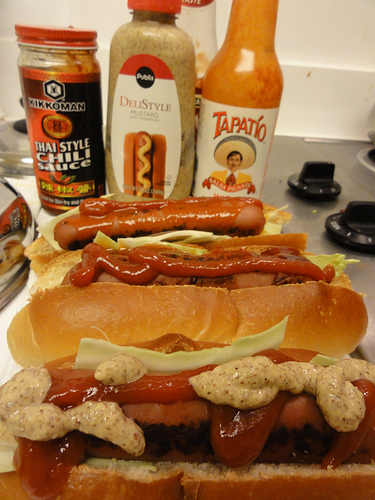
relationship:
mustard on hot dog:
[2, 348, 374, 459] [44, 350, 373, 463]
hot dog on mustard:
[44, 350, 373, 463] [2, 348, 374, 459]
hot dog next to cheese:
[44, 350, 373, 463] [72, 313, 288, 375]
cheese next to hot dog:
[72, 313, 288, 375] [44, 350, 373, 463]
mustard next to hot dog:
[2, 348, 374, 459] [44, 350, 373, 463]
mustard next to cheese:
[2, 348, 374, 459] [72, 313, 288, 375]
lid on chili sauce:
[10, 17, 97, 52] [13, 23, 105, 206]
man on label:
[210, 134, 259, 186] [191, 92, 281, 198]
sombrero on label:
[211, 132, 258, 167] [195, 98, 280, 201]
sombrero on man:
[211, 132, 258, 167] [202, 131, 259, 183]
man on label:
[202, 131, 259, 183] [195, 98, 280, 201]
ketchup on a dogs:
[66, 238, 338, 288] [61, 254, 325, 284]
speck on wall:
[303, 70, 311, 76] [1, 1, 374, 142]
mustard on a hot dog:
[95, 351, 148, 383] [0, 272, 372, 497]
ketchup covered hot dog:
[27, 55, 115, 216] [44, 174, 344, 296]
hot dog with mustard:
[44, 350, 373, 463] [2, 348, 374, 459]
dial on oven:
[288, 159, 343, 201] [264, 135, 374, 362]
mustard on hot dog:
[2, 348, 374, 459] [0, 313, 374, 499]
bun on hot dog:
[19, 332, 374, 499] [0, 313, 374, 499]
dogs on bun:
[61, 254, 325, 284] [6, 246, 368, 366]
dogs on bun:
[53, 200, 267, 250] [24, 204, 291, 276]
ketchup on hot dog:
[8, 365, 369, 490] [0, 313, 374, 499]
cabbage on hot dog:
[72, 313, 290, 375] [0, 313, 374, 499]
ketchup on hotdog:
[75, 237, 338, 283] [93, 242, 360, 352]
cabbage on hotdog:
[75, 314, 291, 374] [1, 334, 374, 499]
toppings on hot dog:
[67, 227, 361, 286] [6, 228, 367, 370]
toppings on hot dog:
[78, 197, 262, 217] [25, 192, 294, 276]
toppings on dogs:
[1, 195, 374, 493] [2, 191, 371, 496]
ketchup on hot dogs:
[77, 195, 265, 219] [50, 191, 273, 237]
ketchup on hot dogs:
[75, 237, 338, 283] [60, 246, 330, 288]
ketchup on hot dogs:
[13, 369, 362, 465] [4, 346, 372, 459]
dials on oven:
[287, 154, 372, 251] [264, 135, 374, 362]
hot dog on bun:
[121, 389, 373, 462] [19, 332, 374, 499]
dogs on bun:
[53, 200, 267, 250] [26, 191, 291, 275]